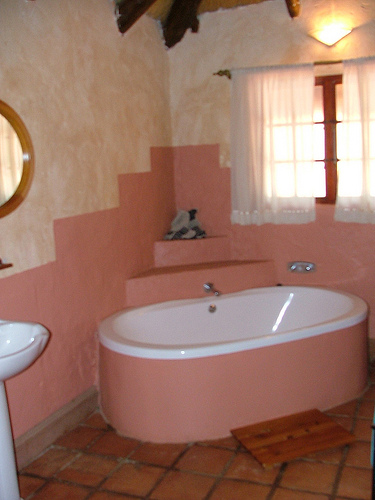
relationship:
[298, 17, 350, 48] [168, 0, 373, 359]
light fixture hanging on wall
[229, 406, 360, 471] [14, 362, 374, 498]
board lying on floor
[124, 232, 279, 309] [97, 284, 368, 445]
shelf are behind bathtub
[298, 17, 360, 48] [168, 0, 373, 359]
light fixture attached to wall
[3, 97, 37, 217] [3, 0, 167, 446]
mirror hanging on wall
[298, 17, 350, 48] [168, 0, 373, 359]
light fixture attached to wall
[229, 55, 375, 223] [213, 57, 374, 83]
curtain has a rod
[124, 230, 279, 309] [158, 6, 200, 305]
shelf in corner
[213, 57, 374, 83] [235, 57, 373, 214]
rod over window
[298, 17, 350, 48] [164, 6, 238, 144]
light fixture attached to wall